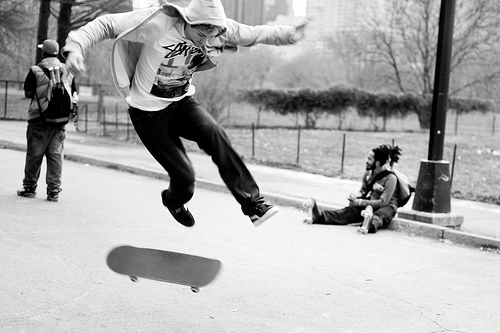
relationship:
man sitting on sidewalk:
[302, 144, 415, 235] [1, 117, 498, 257]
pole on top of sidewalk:
[415, 0, 454, 200] [459, 201, 499, 248]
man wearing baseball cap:
[14, 41, 81, 201] [36, 36, 60, 55]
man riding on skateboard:
[68, 4, 302, 230] [102, 228, 249, 288]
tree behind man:
[0, 0, 500, 132] [60, 0, 313, 227]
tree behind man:
[367, 3, 437, 109] [60, 0, 313, 227]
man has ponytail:
[302, 144, 415, 235] [375, 142, 401, 167]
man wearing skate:
[302, 144, 415, 235] [302, 196, 321, 224]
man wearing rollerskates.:
[302, 144, 415, 235] [302, 196, 379, 233]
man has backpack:
[14, 41, 81, 201] [39, 79, 74, 124]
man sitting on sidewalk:
[302, 144, 415, 235] [276, 165, 498, 249]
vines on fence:
[248, 83, 482, 132] [253, 118, 354, 172]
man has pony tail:
[302, 144, 415, 235] [380, 140, 405, 166]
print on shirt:
[151, 43, 199, 98] [124, 22, 198, 111]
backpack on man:
[33, 58, 75, 127] [14, 41, 81, 201]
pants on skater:
[123, 96, 265, 213] [59, 0, 284, 232]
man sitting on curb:
[302, 144, 415, 235] [3, 128, 495, 251]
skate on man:
[306, 195, 321, 224] [305, 142, 406, 234]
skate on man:
[357, 201, 376, 232] [305, 142, 406, 234]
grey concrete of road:
[89, 257, 213, 302] [61, 180, 393, 330]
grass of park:
[268, 130, 497, 185] [3, 0, 496, 331]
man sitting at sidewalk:
[302, 144, 415, 235] [1, 128, 499, 251]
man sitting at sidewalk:
[291, 146, 415, 229] [1, 128, 499, 251]